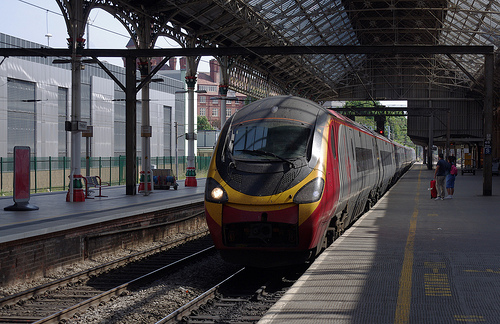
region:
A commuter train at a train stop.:
[9, 3, 491, 310]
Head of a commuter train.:
[197, 92, 350, 268]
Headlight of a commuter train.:
[195, 172, 238, 219]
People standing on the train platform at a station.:
[410, 136, 475, 231]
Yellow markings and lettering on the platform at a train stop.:
[384, 172, 471, 322]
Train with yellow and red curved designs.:
[186, 107, 367, 274]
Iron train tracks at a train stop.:
[14, 218, 319, 320]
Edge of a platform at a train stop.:
[0, 180, 200, 315]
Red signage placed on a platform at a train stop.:
[3, 135, 45, 230]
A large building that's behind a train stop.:
[160, 50, 260, 133]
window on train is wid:
[222, 102, 307, 159]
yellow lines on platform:
[394, 147, 425, 322]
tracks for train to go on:
[119, 252, 264, 317]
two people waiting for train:
[436, 140, 458, 224]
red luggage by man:
[429, 172, 442, 212]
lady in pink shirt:
[452, 156, 457, 181]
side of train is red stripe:
[313, 126, 339, 251]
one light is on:
[198, 176, 224, 212]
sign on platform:
[0, 140, 37, 217]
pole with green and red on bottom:
[58, 157, 91, 217]